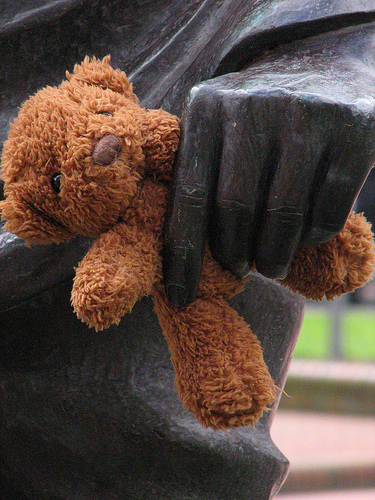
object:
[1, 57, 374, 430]
teddy bear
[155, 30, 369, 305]
hand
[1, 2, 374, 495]
statue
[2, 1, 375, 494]
left side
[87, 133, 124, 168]
nose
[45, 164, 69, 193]
eyes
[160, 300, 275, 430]
right leg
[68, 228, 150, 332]
right arm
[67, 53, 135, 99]
ear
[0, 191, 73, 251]
ear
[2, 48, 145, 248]
head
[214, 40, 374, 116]
reflection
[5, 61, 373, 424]
fur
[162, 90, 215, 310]
finger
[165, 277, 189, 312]
nail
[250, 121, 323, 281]
fingers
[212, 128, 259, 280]
finger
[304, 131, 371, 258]
pinky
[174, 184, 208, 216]
wrinkle